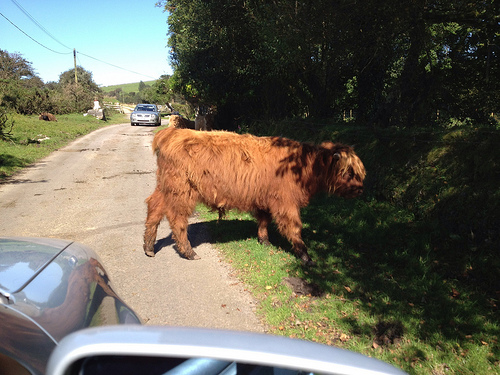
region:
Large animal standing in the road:
[128, 126, 385, 277]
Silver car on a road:
[120, 90, 170, 128]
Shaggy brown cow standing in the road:
[124, 127, 393, 274]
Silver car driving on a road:
[121, 89, 168, 137]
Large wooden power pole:
[63, 41, 80, 111]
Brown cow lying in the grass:
[32, 106, 62, 129]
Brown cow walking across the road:
[123, 120, 400, 267]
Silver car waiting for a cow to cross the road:
[120, 97, 172, 138]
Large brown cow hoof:
[180, 242, 212, 269]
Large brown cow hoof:
[142, 234, 158, 266]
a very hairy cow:
[121, 100, 386, 272]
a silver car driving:
[100, 90, 185, 130]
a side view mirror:
[48, 250, 413, 371]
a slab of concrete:
[68, 177, 123, 214]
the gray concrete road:
[23, 85, 277, 355]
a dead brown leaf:
[331, 318, 363, 347]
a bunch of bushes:
[17, 80, 110, 122]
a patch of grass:
[384, 236, 446, 296]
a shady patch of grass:
[282, 195, 477, 355]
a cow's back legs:
[141, 163, 225, 262]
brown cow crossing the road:
[122, 102, 444, 257]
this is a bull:
[158, 129, 365, 256]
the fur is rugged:
[205, 145, 275, 201]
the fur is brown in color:
[197, 141, 268, 181]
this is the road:
[51, 137, 112, 217]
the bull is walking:
[145, 131, 335, 258]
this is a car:
[127, 100, 157, 120]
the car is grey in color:
[135, 106, 145, 116]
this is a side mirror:
[57, 330, 392, 372]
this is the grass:
[38, 122, 74, 134]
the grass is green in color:
[25, 123, 79, 130]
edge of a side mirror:
[207, 330, 255, 362]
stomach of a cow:
[211, 175, 252, 209]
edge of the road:
[33, 156, 48, 168]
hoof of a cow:
[183, 247, 200, 264]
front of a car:
[135, 113, 155, 125]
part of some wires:
[24, 7, 64, 59]